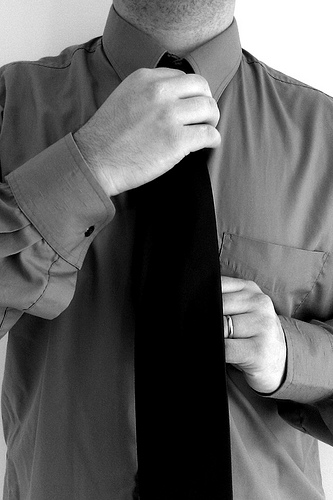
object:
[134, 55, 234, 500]
tie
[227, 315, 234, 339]
ring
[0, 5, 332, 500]
shirt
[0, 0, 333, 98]
wall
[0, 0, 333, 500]
man